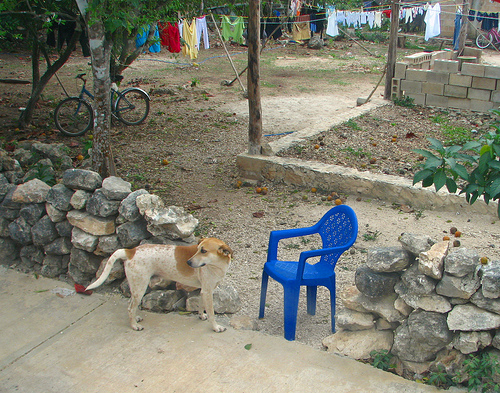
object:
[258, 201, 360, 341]
chair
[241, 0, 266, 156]
wood pole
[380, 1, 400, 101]
wood pole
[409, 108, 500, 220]
tree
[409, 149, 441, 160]
leaf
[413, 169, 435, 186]
leaf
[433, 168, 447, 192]
leaf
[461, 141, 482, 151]
leaf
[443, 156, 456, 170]
leaf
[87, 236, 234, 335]
dog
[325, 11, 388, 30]
laundry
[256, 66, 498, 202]
patio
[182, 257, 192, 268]
nose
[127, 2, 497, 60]
clothes line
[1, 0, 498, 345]
yard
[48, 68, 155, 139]
bicycle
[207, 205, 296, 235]
rocks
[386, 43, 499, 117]
blocks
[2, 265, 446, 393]
cement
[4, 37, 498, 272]
ground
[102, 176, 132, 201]
rock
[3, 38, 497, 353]
dirt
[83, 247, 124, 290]
tail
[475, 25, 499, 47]
bike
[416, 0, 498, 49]
house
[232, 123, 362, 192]
curbing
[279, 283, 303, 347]
leg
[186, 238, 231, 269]
head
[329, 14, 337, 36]
clothes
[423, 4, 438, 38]
clothes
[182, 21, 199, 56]
clothes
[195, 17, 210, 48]
clothes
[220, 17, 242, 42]
clothes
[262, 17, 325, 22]
line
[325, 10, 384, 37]
white clothes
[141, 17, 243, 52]
clothes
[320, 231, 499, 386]
wall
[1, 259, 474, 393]
sidewalk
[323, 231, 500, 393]
fence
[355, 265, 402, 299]
rock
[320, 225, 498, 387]
stones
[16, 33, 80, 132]
tree trunk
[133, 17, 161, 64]
clothes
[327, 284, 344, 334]
legs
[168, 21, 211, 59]
garment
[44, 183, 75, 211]
rocks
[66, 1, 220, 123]
tree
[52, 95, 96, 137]
wheels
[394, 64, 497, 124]
wall